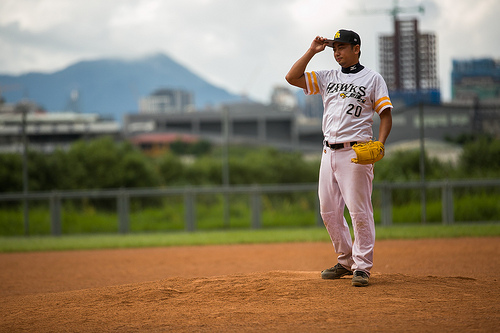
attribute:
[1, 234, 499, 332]
court — red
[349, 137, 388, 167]
mitt — yellow, leather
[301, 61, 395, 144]
shirt — white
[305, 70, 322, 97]
stripes — yellow, orange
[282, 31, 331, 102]
arm — bend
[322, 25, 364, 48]
cap — black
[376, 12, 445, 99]
building — rise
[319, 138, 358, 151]
belt — black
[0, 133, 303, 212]
trees — green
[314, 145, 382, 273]
pants — white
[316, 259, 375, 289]
shoes — black